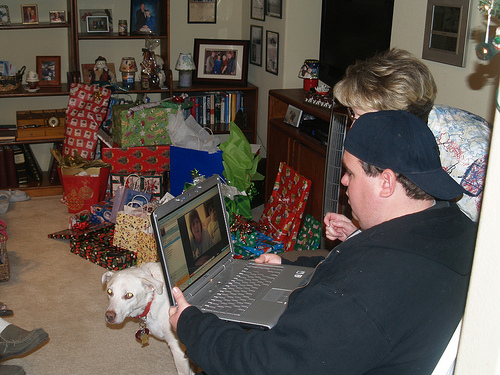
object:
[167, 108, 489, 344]
cap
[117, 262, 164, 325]
collar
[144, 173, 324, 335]
laptop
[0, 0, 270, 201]
shelf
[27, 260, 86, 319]
carpet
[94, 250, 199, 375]
dog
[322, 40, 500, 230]
woman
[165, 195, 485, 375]
sweatshirt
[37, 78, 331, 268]
gifts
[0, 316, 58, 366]
shoe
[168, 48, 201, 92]
lamp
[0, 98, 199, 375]
floor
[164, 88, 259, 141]
books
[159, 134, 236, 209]
bag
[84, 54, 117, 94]
decorations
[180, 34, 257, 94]
frame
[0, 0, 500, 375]
livingroom